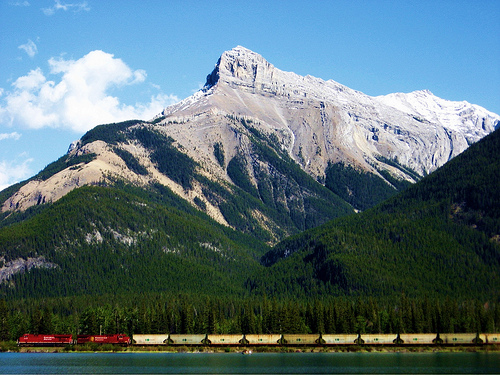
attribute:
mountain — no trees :
[120, 46, 422, 200]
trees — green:
[4, 122, 499, 335]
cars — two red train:
[16, 331, 74, 345]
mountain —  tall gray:
[126, 37, 493, 211]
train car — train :
[16, 331, 77, 346]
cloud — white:
[1, 48, 180, 133]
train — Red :
[22, 290, 493, 367]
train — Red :
[13, 331, 498, 348]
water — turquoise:
[143, 333, 461, 373]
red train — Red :
[14, 331, 134, 348]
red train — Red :
[25, 330, 87, 357]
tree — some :
[246, 308, 264, 335]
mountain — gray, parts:
[0, 45, 499, 330]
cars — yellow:
[161, 314, 358, 362]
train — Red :
[16, 330, 133, 345]